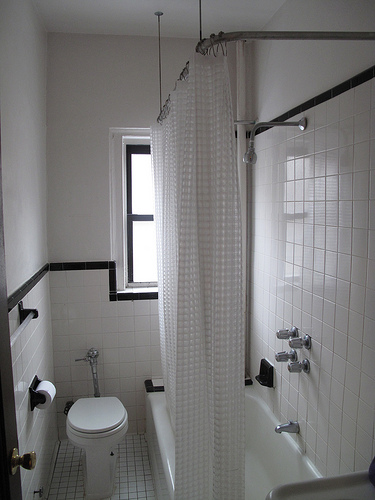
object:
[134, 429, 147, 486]
tiles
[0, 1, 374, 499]
bathroom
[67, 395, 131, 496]
toilet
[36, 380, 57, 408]
paper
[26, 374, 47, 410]
rack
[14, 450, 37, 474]
knob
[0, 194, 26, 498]
door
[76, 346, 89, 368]
flusher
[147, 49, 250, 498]
curtain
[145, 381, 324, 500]
bathtub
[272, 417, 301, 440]
nozzle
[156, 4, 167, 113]
rod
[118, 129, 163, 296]
window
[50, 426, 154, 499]
floor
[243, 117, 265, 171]
shower head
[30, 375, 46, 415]
paper roll holder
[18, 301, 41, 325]
towel bar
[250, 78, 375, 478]
wall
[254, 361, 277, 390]
soap holder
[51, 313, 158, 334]
tile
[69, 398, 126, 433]
toilet lid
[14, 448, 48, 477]
nob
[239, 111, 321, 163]
shower bar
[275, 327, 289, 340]
fixture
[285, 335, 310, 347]
fixture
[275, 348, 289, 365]
fixture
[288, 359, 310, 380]
fixture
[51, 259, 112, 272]
tile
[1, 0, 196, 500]
on wall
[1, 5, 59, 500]
wall